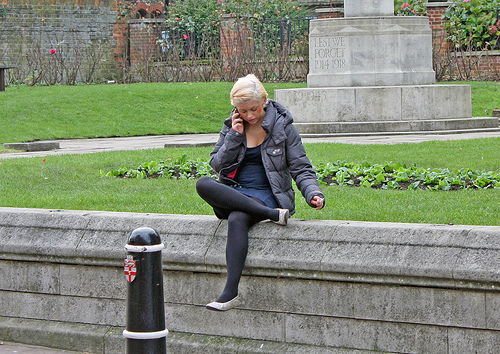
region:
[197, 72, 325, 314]
woman is talking on phone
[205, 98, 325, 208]
woman's jacket is gray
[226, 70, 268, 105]
woman's hair is blonde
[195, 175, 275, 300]
woman is wearing stockings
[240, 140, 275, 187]
woman's shirt is black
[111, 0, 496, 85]
wall made of brick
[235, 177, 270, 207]
woman's skirt is blue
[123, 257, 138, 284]
red and white sign on cigarette post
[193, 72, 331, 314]
the woman is looking down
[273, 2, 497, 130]
concrete statue behind woman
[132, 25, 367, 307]
A girl sitting on a wall ledge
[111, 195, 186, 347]
A black pole with white trim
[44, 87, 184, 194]
A green grassy lawn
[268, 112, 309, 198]
A grey colored jacket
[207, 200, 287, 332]
A light grey pair of shoes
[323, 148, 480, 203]
Plant bed behind girl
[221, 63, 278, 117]
A girl with blonde hair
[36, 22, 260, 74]
Shrubs with no leaves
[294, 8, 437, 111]
A statue behind girl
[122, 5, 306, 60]
Brick columns behind shrubs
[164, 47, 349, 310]
a girl sitting on wall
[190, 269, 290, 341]
white flats on feet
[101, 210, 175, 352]
a black and white pole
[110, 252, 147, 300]
a red cross on pole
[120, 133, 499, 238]
an area of planted crops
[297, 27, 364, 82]
letters carved into concrete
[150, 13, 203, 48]
small red flowers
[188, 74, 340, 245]
a gray heavy jacket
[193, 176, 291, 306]
black stockings on legs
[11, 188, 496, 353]
a short concrete wall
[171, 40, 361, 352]
a girl sitting on a wall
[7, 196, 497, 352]
a short concrete wall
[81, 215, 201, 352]
a black and white pole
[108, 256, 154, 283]
a red cross on pole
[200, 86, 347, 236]
a heavy gray jackte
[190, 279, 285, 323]
white shoes on feet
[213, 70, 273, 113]
blond hair on head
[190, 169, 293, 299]
black stockings on legs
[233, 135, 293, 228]
a blue shirt and blue skirt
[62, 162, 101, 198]
this is the grass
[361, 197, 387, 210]
the grass is short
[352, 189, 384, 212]
the grass is green in color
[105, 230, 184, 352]
this is a post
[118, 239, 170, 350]
the post is metallic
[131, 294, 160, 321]
the post is black in color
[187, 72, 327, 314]
this is a woman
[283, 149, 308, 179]
the jacket is grey in color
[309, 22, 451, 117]
this is a block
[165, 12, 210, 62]
these are some flowers